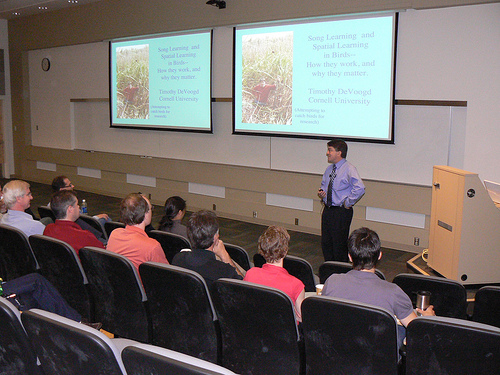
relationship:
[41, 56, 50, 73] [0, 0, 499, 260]
clock on wall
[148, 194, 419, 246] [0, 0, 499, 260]
outlets are on wall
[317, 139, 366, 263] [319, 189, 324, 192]
man has a remote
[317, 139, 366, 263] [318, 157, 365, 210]
man wearing a shirt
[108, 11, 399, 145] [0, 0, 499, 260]
screens are on wall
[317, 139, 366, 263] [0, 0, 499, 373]
man in room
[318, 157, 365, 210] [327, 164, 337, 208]
shirt has a purple tie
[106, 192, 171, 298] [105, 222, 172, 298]
man wearing an orange shirt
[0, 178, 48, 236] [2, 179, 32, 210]
man has grey hair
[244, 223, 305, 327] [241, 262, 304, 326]
woman wearing a shirt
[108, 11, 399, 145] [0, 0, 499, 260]
slide show on a wall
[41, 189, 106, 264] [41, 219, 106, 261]
man wearing a red shirt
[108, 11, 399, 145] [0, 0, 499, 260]
slide show on wall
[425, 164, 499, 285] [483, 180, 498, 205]
podium has equipment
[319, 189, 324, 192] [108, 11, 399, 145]
remote for slide show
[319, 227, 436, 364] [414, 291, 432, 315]
person holding thermos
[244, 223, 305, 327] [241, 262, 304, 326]
woman wearing a red shirt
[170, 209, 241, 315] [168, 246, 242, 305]
man wearing a black shirt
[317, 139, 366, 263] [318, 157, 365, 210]
man wearing a blue shirt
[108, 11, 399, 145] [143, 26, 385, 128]
slide show has writing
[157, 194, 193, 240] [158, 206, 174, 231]
man has a pony tail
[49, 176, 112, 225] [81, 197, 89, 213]
man holding water bottle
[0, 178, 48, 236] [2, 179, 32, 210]
man has white hair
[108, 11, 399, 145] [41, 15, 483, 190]
slide show on wall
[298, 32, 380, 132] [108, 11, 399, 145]
writing on slide show